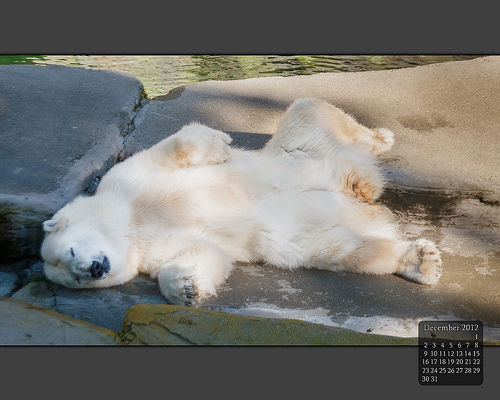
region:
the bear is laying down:
[47, 95, 427, 306]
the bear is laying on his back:
[42, 99, 447, 297]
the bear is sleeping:
[39, 88, 437, 305]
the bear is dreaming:
[38, 101, 436, 311]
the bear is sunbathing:
[41, 103, 440, 305]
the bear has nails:
[183, 275, 195, 309]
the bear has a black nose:
[93, 263, 105, 282]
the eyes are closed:
[66, 245, 82, 289]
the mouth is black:
[101, 254, 108, 271]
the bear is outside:
[0, 3, 497, 395]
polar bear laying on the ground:
[40, 98, 442, 306]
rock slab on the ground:
[6, 68, 497, 316]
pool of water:
[5, 56, 433, 88]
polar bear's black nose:
[89, 262, 103, 279]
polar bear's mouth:
[103, 258, 108, 273]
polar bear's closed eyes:
[72, 245, 80, 281]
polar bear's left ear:
[43, 217, 58, 232]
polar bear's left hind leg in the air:
[288, 104, 395, 159]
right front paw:
[158, 261, 198, 306]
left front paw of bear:
[182, 123, 232, 166]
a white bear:
[36, 97, 442, 307]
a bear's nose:
[85, 255, 102, 277]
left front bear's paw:
[170, 120, 230, 165]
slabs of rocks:
[5, 56, 496, 341]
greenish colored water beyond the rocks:
[0, 55, 495, 90]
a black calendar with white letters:
[415, 316, 485, 386]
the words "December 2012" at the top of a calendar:
[422, 320, 477, 330]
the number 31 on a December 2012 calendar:
[430, 372, 435, 382]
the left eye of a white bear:
[65, 245, 75, 256]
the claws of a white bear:
[183, 275, 195, 308]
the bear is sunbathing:
[48, 104, 438, 308]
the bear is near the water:
[3, 55, 478, 92]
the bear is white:
[48, 98, 442, 307]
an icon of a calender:
[419, 323, 486, 385]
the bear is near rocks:
[4, 53, 497, 346]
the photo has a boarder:
[0, 1, 499, 398]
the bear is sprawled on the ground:
[44, 98, 437, 303]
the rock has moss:
[1, 298, 499, 347]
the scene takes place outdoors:
[0, 53, 498, 345]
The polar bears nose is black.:
[86, 260, 101, 279]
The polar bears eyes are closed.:
[68, 245, 83, 287]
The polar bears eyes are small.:
[63, 248, 84, 288]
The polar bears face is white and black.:
[38, 213, 135, 293]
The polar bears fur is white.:
[141, 165, 236, 242]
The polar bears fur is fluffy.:
[142, 178, 269, 225]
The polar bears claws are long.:
[177, 268, 198, 311]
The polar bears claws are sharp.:
[183, 274, 202, 305]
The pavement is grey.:
[16, 86, 105, 161]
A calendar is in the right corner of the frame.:
[412, 313, 489, 391]